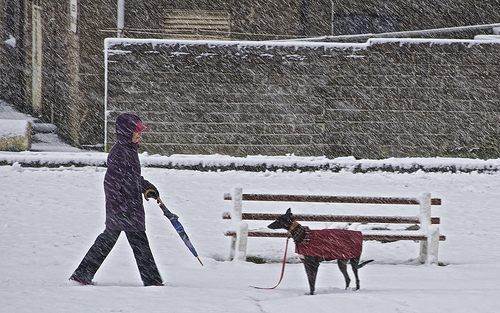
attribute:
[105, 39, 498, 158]
wall — brick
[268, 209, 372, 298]
blanket — red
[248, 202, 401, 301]
dog — standing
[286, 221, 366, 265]
outfit — red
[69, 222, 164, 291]
pants — black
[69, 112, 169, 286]
woman — walking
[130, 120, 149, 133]
hat — pink